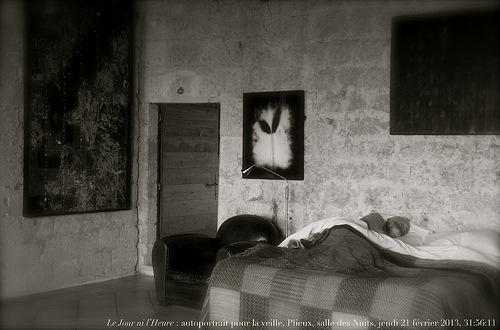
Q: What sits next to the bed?
A: A leather chair.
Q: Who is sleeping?
A: The man in the bed.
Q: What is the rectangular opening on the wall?
A: Door.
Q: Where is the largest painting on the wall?
A: Next to the door to the left.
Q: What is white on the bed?
A: Sheet.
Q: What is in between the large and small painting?
A: Doorway.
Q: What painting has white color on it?
A: Small painting on wall.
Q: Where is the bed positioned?
A: Against the wall.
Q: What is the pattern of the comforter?
A: Checkered.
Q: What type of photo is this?
A: Black and white.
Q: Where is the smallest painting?
A: Above the chair.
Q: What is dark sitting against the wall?
A: Chair.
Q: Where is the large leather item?
A: Next to bed.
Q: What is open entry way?
A: Door.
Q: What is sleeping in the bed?
A: A human.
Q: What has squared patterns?
A: Blanket.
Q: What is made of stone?
A: Wall.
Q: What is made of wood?
A: Door.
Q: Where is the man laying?
A: In bed.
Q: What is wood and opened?
A: Door.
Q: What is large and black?
A: Picture.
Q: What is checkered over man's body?
A: Blanket.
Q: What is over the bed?
A: A picture.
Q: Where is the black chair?
A: Beside the bed.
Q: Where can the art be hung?
A: The white stone walls.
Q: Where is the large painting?
A: On the side wall.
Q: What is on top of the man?
A: A bedspread.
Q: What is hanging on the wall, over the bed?
A: A painting.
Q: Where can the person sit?
A: In the chair.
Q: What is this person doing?
A: Sleeping.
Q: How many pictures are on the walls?
A: Three.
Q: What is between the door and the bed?
A: A chair.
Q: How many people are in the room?
A: One.